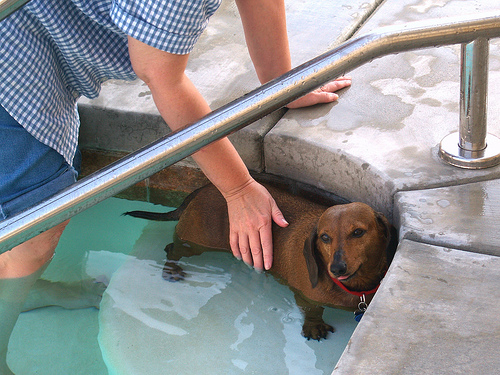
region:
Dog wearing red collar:
[289, 198, 378, 307]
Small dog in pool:
[159, 193, 385, 325]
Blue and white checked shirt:
[0, 5, 207, 114]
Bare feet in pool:
[0, 145, 106, 348]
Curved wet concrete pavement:
[277, 107, 441, 199]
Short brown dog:
[165, 191, 388, 326]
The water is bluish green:
[67, 216, 138, 278]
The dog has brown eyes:
[300, 199, 380, 290]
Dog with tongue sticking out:
[303, 195, 375, 299]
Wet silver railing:
[223, 19, 474, 136]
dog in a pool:
[122, 161, 415, 358]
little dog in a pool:
[135, 168, 424, 344]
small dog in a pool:
[115, 162, 416, 351]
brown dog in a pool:
[116, 154, 421, 353]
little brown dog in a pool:
[107, 158, 412, 363]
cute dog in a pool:
[93, 157, 413, 348]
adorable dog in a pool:
[85, 147, 429, 351]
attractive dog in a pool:
[105, 146, 405, 360]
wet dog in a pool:
[105, 133, 426, 356]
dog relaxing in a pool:
[118, 123, 413, 354]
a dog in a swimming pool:
[125, 173, 398, 352]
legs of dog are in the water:
[119, 157, 394, 349]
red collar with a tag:
[319, 276, 377, 321]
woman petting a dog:
[1, 3, 348, 299]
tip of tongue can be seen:
[324, 253, 357, 288]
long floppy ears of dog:
[291, 205, 391, 295]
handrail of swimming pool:
[0, 13, 497, 231]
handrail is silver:
[1, 8, 499, 261]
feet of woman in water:
[3, 272, 119, 369]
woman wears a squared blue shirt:
[0, 3, 350, 366]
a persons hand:
[215, 175, 281, 267]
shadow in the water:
[193, 296, 293, 373]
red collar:
[332, 276, 376, 296]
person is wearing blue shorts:
[0, 139, 53, 194]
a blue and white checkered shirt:
[11, 19, 101, 91]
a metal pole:
[376, 18, 489, 52]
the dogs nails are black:
[307, 330, 328, 341]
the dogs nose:
[327, 262, 348, 277]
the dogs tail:
[127, 209, 188, 220]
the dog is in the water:
[285, 200, 367, 334]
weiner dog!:
[119, 174, 401, 341]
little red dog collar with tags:
[326, 274, 379, 324]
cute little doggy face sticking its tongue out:
[302, 202, 399, 292]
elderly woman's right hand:
[225, 184, 290, 274]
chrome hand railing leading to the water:
[0, 13, 499, 257]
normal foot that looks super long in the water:
[19, 274, 107, 313]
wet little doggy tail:
[119, 183, 201, 224]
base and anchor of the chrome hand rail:
[435, 126, 498, 172]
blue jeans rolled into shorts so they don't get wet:
[0, 102, 82, 220]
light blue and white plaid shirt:
[0, 0, 223, 170]